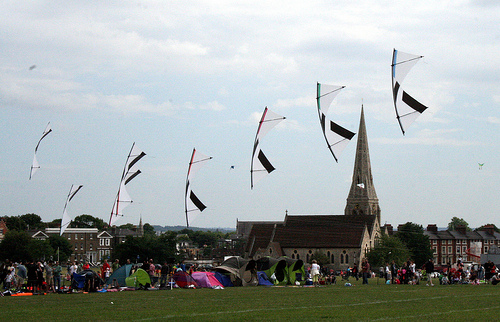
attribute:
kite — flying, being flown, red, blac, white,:
[23, 117, 58, 185]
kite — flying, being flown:
[57, 173, 85, 241]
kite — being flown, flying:
[104, 120, 149, 235]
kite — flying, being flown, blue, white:
[181, 136, 213, 230]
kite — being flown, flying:
[243, 94, 288, 189]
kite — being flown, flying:
[305, 68, 358, 163]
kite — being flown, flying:
[385, 43, 432, 136]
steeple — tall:
[346, 92, 394, 221]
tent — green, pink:
[255, 253, 287, 286]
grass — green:
[3, 274, 499, 319]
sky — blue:
[1, 2, 498, 226]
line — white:
[155, 286, 497, 319]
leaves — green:
[3, 228, 73, 263]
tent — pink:
[187, 268, 222, 290]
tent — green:
[280, 253, 305, 284]